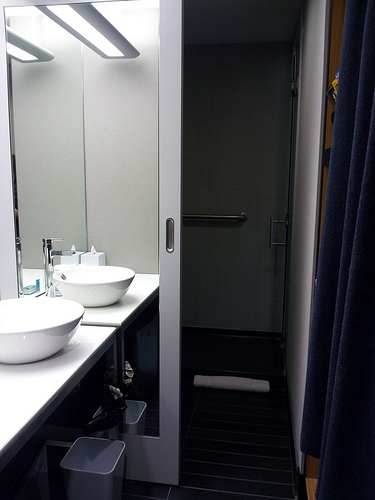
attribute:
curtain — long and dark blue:
[298, 1, 374, 494]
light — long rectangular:
[30, 3, 142, 60]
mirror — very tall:
[124, 172, 241, 396]